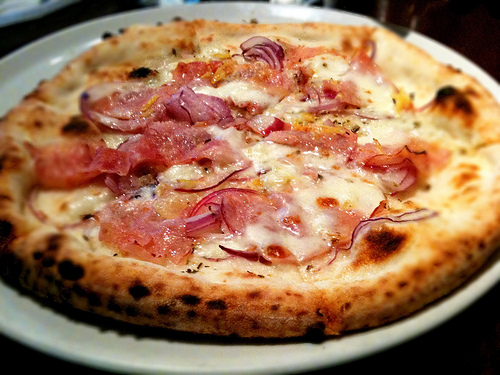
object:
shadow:
[71, 294, 276, 349]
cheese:
[11, 35, 488, 287]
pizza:
[40, 36, 433, 300]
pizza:
[17, 13, 462, 280]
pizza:
[7, 21, 499, 373]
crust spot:
[434, 82, 475, 103]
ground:
[293, 180, 349, 223]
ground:
[388, 179, 428, 216]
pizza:
[119, 28, 283, 72]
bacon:
[17, 114, 243, 190]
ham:
[95, 116, 255, 223]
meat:
[86, 115, 237, 185]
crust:
[132, 260, 217, 332]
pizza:
[113, 115, 298, 302]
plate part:
[373, 330, 421, 348]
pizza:
[5, 12, 494, 345]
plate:
[5, 4, 497, 370]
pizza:
[227, 272, 248, 296]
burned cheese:
[422, 82, 487, 134]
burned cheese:
[354, 219, 411, 257]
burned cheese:
[117, 57, 164, 83]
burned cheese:
[49, 107, 106, 143]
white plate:
[33, 308, 202, 373]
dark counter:
[373, 310, 497, 374]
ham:
[95, 78, 219, 149]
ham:
[349, 133, 429, 195]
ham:
[164, 87, 211, 128]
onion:
[356, 205, 434, 229]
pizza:
[50, 40, 405, 301]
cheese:
[249, 190, 346, 245]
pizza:
[22, 48, 449, 292]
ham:
[117, 88, 220, 125]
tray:
[3, 3, 499, 373]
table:
[3, 1, 499, 372]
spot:
[0, 213, 20, 251]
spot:
[29, 231, 65, 276]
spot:
[52, 255, 89, 285]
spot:
[125, 276, 154, 305]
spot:
[112, 298, 154, 321]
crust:
[0, 253, 326, 344]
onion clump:
[240, 31, 288, 72]